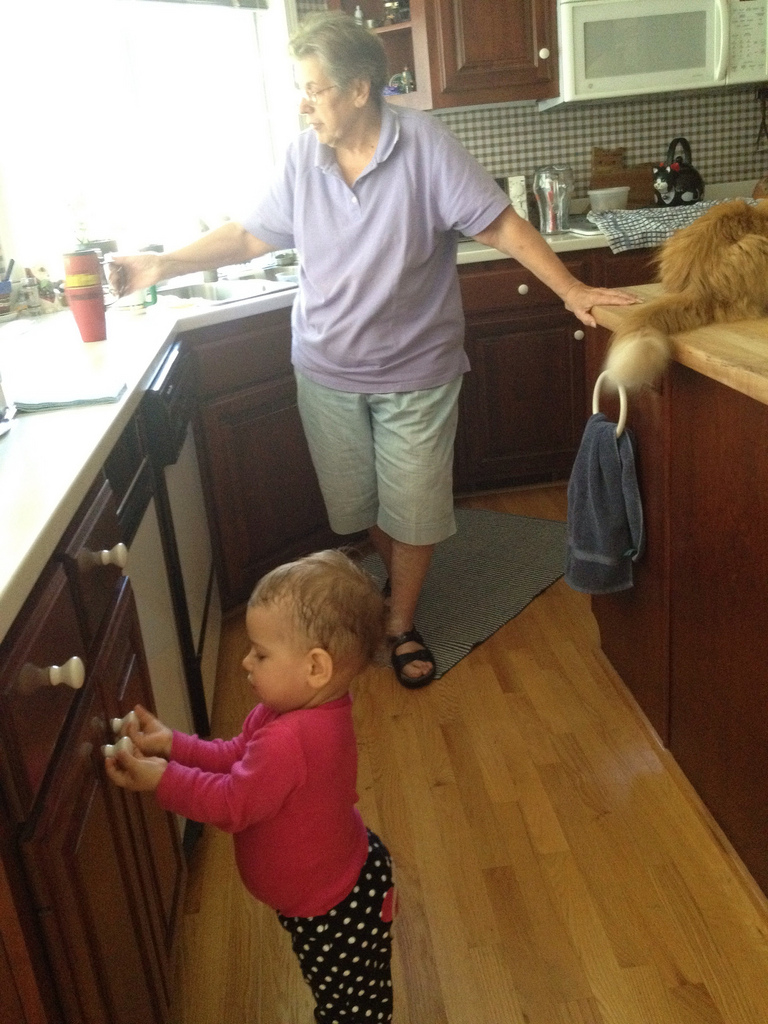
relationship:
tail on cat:
[607, 309, 668, 380] [638, 171, 759, 378]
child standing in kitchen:
[97, 538, 399, 1021] [0, 22, 762, 1017]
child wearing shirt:
[103, 540, 401, 1024] [158, 697, 374, 896]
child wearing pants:
[103, 540, 401, 1024] [280, 827, 394, 1021]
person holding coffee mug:
[105, 14, 639, 690] [56, 250, 110, 345]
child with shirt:
[103, 540, 401, 1024] [195, 697, 370, 885]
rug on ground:
[572, 421, 648, 581] [387, 732, 606, 847]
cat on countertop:
[608, 198, 767, 347] [574, 269, 760, 876]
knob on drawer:
[74, 520, 133, 574] [66, 479, 144, 629]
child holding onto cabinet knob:
[103, 540, 401, 1024] [98, 733, 141, 768]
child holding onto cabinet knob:
[103, 540, 401, 1024] [109, 705, 148, 744]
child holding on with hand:
[103, 540, 401, 1024] [94, 734, 173, 799]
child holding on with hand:
[103, 540, 401, 1024] [112, 703, 180, 761]